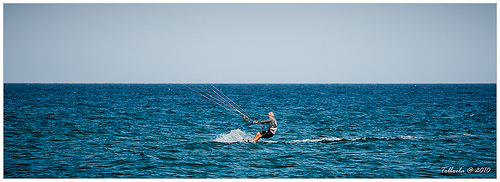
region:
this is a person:
[237, 97, 282, 142]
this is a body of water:
[296, 97, 356, 167]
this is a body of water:
[403, 118, 448, 169]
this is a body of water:
[63, 112, 125, 164]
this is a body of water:
[162, 107, 212, 173]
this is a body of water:
[68, 94, 118, 136]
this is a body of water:
[299, 98, 369, 145]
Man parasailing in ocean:
[245, 108, 277, 148]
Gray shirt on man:
[259, 117, 276, 127]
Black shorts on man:
[260, 127, 281, 139]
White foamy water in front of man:
[211, 129, 249, 141]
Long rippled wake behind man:
[274, 133, 450, 145]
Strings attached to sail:
[190, 78, 250, 122]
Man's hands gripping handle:
[253, 116, 260, 123]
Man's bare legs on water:
[247, 130, 259, 144]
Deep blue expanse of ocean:
[5, 81, 498, 173]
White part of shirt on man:
[267, 125, 281, 133]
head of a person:
[260, 99, 278, 124]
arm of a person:
[254, 116, 269, 126]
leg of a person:
[243, 127, 274, 145]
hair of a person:
[270, 103, 279, 113]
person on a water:
[226, 90, 303, 167]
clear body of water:
[19, 80, 186, 142]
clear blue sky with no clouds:
[301, 24, 482, 71]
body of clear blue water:
[33, 108, 113, 143]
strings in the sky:
[125, 34, 267, 124]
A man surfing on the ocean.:
[243, 110, 279, 144]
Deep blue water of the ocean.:
[5, 81, 499, 179]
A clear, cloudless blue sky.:
[5, 5, 497, 86]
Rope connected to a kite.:
[190, 85, 251, 120]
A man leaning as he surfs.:
[240, 110, 279, 145]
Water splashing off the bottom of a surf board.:
[213, 128, 258, 142]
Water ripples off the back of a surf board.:
[264, 134, 459, 142]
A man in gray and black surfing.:
[243, 110, 279, 145]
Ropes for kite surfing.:
[190, 83, 248, 120]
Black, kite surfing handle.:
[243, 115, 259, 127]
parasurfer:
[249, 93, 294, 150]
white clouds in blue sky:
[60, 8, 99, 38]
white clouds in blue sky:
[339, 9, 377, 49]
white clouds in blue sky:
[385, 36, 425, 68]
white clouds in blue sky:
[151, 35, 206, 87]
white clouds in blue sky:
[240, 28, 287, 73]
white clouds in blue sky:
[309, 24, 347, 70]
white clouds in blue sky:
[374, 15, 404, 59]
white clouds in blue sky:
[150, 15, 203, 57]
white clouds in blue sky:
[208, 15, 253, 69]